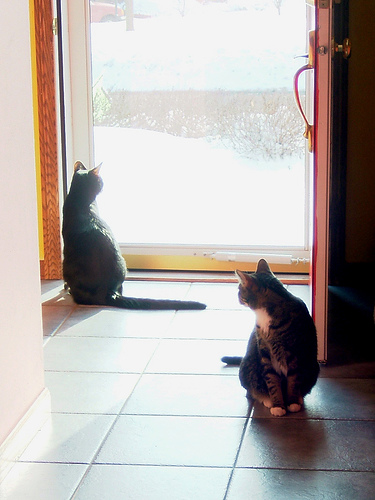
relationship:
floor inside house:
[2, 279, 375, 500] [4, 1, 374, 500]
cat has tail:
[59, 159, 209, 316] [113, 295, 206, 313]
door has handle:
[292, 5, 350, 364] [334, 37, 352, 60]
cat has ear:
[224, 254, 320, 416] [236, 269, 253, 287]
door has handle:
[292, 5, 350, 364] [292, 30, 315, 154]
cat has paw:
[224, 254, 320, 416] [269, 402, 287, 418]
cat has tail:
[224, 254, 320, 416] [221, 354, 248, 366]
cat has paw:
[224, 254, 320, 416] [287, 398, 304, 413]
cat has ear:
[59, 159, 209, 316] [87, 162, 105, 176]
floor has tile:
[2, 279, 375, 500] [93, 413, 247, 468]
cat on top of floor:
[224, 254, 320, 416] [2, 279, 375, 500]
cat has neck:
[224, 254, 320, 416] [250, 292, 293, 326]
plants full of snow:
[91, 90, 316, 162] [94, 159, 308, 217]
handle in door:
[331, 37, 353, 56] [292, 5, 350, 364]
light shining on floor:
[49, 302, 146, 428] [2, 279, 375, 500]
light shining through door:
[45, 313, 154, 406] [292, 5, 350, 364]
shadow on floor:
[250, 401, 329, 492] [60, 342, 220, 496]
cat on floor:
[224, 254, 320, 416] [60, 342, 220, 496]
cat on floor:
[59, 159, 209, 316] [60, 342, 220, 496]